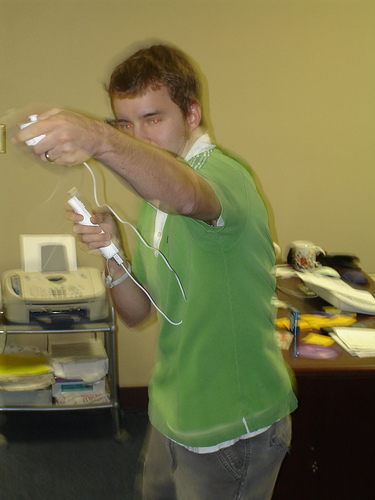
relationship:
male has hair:
[12, 43, 299, 499] [101, 44, 206, 136]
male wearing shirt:
[12, 43, 299, 499] [131, 132, 299, 447]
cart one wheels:
[0, 289, 133, 446] [0, 408, 129, 444]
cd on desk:
[294, 344, 338, 359] [272, 260, 374, 499]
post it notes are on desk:
[274, 306, 357, 346] [272, 260, 374, 499]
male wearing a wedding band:
[12, 43, 299, 499] [43, 151, 53, 163]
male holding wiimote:
[12, 43, 299, 499] [69, 196, 120, 260]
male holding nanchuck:
[12, 43, 299, 499] [19, 114, 47, 148]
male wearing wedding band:
[12, 43, 299, 499] [43, 151, 53, 163]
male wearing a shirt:
[12, 43, 299, 499] [131, 132, 299, 447]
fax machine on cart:
[4, 244, 108, 331] [0, 289, 133, 446]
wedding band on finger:
[43, 151, 53, 163] [41, 145, 63, 162]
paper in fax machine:
[20, 235, 79, 273] [4, 244, 108, 331]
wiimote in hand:
[69, 196, 120, 260] [65, 211, 123, 256]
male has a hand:
[12, 43, 299, 499] [65, 211, 123, 256]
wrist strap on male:
[105, 259, 133, 288] [12, 43, 299, 499]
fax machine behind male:
[4, 244, 108, 331] [12, 43, 299, 499]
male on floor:
[12, 43, 299, 499] [0, 409, 147, 499]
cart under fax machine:
[0, 289, 133, 446] [4, 244, 108, 331]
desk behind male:
[272, 260, 374, 499] [12, 43, 299, 499]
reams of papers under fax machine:
[0, 340, 112, 408] [4, 244, 108, 331]